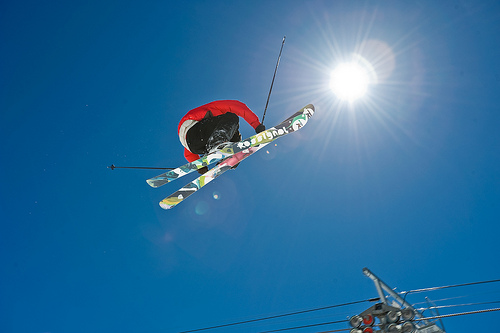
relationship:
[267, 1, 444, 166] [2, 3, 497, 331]
sun in sky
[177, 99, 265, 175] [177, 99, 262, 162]
man in coat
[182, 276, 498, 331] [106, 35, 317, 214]
wire for skier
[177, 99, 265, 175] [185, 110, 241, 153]
man wears pants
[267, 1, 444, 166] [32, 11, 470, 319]
sun brightly in sky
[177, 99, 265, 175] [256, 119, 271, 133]
man wears glove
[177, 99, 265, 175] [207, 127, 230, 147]
man wears shoe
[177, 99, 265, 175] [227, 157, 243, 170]
man wears shoe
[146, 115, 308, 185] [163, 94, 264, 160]
ski of skier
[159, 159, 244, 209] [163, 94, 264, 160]
ski of skier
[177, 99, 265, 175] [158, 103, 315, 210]
man wears ski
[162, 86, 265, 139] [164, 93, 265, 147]
man wearing coat